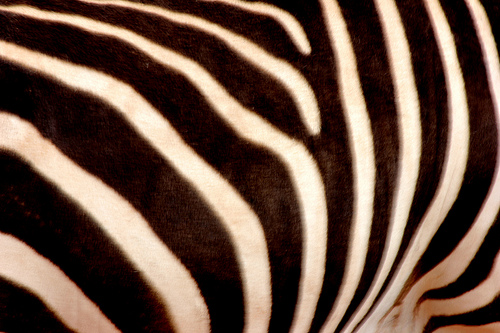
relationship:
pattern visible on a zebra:
[1, 2, 499, 333] [0, 1, 499, 332]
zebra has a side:
[0, 1, 499, 332] [4, 4, 499, 333]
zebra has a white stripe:
[0, 1, 499, 332] [315, 1, 380, 332]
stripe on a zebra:
[0, 39, 274, 333] [0, 1, 499, 332]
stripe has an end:
[207, 2, 313, 57] [294, 32, 315, 59]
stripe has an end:
[411, 2, 499, 303] [396, 250, 456, 290]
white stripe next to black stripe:
[315, 1, 380, 332] [337, 1, 403, 333]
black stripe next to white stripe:
[337, 1, 403, 333] [315, 1, 380, 332]